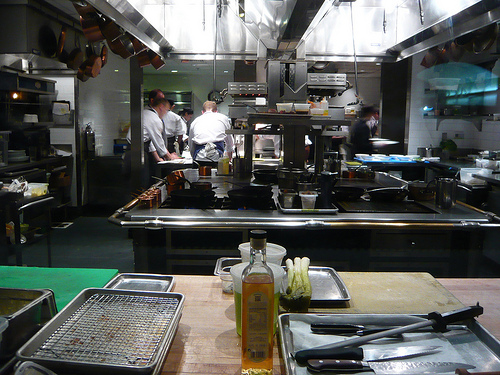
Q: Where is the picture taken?
A: In a kitchen.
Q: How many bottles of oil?
A: One.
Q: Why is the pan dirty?
A: Food was cooked on it.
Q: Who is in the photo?
A: Restaurant staff.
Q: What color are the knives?
A: Silver and black.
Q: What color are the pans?
A: Silver.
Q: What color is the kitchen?
A: Steel.